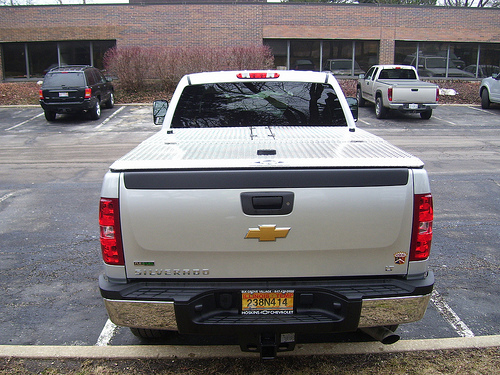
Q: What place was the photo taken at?
A: It was taken at the parking lot.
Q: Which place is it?
A: It is a parking lot.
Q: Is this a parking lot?
A: Yes, it is a parking lot.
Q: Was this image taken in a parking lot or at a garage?
A: It was taken at a parking lot.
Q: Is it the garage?
A: No, it is the parking lot.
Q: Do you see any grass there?
A: Yes, there is grass.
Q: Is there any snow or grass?
A: Yes, there is grass.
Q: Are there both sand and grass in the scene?
A: No, there is grass but no sand.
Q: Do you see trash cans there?
A: No, there are no trash cans.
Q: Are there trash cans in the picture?
A: No, there are no trash cans.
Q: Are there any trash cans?
A: No, there are no trash cans.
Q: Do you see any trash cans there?
A: No, there are no trash cans.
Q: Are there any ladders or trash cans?
A: No, there are no trash cans or ladders.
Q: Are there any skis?
A: No, there are no skis.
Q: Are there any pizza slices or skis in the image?
A: No, there are no skis or pizza slices.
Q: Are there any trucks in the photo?
A: Yes, there is a truck.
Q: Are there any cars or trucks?
A: Yes, there is a truck.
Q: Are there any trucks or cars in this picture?
A: Yes, there is a truck.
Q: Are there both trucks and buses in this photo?
A: No, there is a truck but no buses.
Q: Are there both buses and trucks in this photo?
A: No, there is a truck but no buses.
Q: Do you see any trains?
A: No, there are no trains.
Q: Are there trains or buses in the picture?
A: No, there are no trains or buses.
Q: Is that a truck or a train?
A: That is a truck.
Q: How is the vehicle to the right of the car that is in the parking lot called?
A: The vehicle is a truck.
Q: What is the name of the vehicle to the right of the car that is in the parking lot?
A: The vehicle is a truck.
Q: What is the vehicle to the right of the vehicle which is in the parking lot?
A: The vehicle is a truck.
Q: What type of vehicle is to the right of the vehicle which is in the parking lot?
A: The vehicle is a truck.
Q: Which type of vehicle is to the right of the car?
A: The vehicle is a truck.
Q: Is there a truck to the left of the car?
A: No, the truck is to the right of the car.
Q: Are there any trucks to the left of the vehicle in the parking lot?
A: No, the truck is to the right of the car.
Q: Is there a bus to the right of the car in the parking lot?
A: No, there is a truck to the right of the car.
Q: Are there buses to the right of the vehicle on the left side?
A: No, there is a truck to the right of the car.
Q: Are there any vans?
A: No, there are no vans.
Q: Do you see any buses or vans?
A: No, there are no vans or buses.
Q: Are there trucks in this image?
A: Yes, there is a truck.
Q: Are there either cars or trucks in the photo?
A: Yes, there is a truck.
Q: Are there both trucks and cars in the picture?
A: Yes, there are both a truck and a car.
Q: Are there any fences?
A: No, there are no fences.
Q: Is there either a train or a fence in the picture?
A: No, there are no fences or trains.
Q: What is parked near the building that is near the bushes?
A: The truck is parked near the building.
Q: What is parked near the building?
A: The truck is parked near the building.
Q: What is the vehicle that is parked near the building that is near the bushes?
A: The vehicle is a truck.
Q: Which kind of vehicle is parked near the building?
A: The vehicle is a truck.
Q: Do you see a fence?
A: No, there are no fences.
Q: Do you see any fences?
A: No, there are no fences.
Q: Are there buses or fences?
A: No, there are no fences or buses.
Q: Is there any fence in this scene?
A: No, there are no fences.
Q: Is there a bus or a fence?
A: No, there are no fences or buses.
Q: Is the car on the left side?
A: Yes, the car is on the left of the image.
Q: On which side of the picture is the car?
A: The car is on the left of the image.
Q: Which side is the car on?
A: The car is on the left of the image.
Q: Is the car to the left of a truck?
A: Yes, the car is to the left of a truck.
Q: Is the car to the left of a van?
A: No, the car is to the left of a truck.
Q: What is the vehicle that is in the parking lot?
A: The vehicle is a car.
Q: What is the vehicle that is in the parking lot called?
A: The vehicle is a car.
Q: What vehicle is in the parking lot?
A: The vehicle is a car.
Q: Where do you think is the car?
A: The car is in the parking lot.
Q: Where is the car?
A: The car is in the parking lot.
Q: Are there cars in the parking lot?
A: Yes, there is a car in the parking lot.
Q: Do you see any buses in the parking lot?
A: No, there is a car in the parking lot.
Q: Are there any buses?
A: No, there are no buses.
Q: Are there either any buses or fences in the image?
A: No, there are no buses or fences.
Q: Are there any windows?
A: Yes, there are windows.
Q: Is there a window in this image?
A: Yes, there are windows.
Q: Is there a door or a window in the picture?
A: Yes, there are windows.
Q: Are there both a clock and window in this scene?
A: No, there are windows but no clocks.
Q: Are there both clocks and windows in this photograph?
A: No, there are windows but no clocks.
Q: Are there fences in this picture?
A: No, there are no fences.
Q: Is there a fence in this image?
A: No, there are no fences.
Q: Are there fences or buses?
A: No, there are no fences or buses.